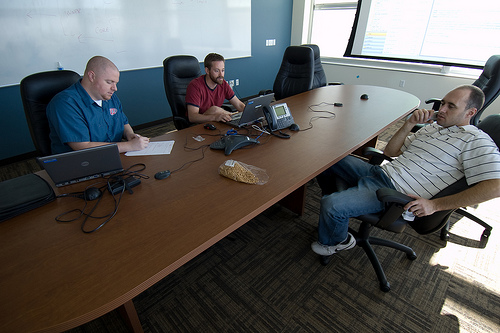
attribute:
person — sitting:
[46, 56, 150, 157]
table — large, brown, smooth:
[0, 84, 421, 333]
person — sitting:
[186, 53, 245, 123]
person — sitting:
[310, 85, 499, 256]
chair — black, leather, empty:
[273, 46, 313, 101]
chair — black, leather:
[163, 55, 200, 131]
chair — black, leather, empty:
[302, 44, 327, 88]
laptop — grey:
[224, 92, 275, 128]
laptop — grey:
[38, 143, 126, 188]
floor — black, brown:
[0, 115, 500, 333]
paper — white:
[125, 140, 175, 156]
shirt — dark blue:
[46, 79, 129, 155]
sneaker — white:
[311, 231, 357, 256]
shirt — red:
[183, 73, 235, 117]